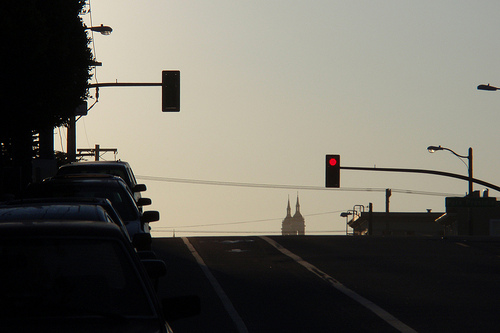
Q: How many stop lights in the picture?
A: 2.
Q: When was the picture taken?
A: Daylight.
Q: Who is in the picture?
A: No one.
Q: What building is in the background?
A: Two towers.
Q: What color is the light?
A: Red.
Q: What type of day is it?
A: Cloudy.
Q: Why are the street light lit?
A: Because it is dark outside.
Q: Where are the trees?
A: On the left side.